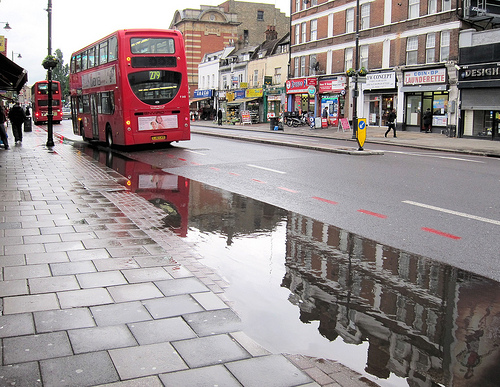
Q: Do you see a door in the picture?
A: Yes, there is a door.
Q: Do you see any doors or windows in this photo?
A: Yes, there is a door.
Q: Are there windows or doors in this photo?
A: Yes, there is a door.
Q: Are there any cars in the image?
A: No, there are no cars.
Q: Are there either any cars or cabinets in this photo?
A: No, there are no cars or cabinets.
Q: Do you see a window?
A: Yes, there is a window.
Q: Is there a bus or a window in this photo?
A: Yes, there is a window.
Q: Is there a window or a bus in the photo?
A: Yes, there is a window.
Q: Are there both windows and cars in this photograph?
A: No, there is a window but no cars.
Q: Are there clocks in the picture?
A: No, there are no clocks.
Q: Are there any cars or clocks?
A: No, there are no clocks or cars.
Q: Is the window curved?
A: Yes, the window is curved.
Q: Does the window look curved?
A: Yes, the window is curved.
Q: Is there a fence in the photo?
A: No, there are no fences.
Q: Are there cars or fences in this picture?
A: No, there are no fences or cars.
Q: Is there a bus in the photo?
A: Yes, there is a bus.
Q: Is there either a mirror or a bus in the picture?
A: Yes, there is a bus.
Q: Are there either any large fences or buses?
A: Yes, there is a large bus.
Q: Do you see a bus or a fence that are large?
A: Yes, the bus is large.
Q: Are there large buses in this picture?
A: Yes, there is a large bus.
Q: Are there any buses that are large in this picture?
A: Yes, there is a large bus.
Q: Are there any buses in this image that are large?
A: Yes, there is a bus that is large.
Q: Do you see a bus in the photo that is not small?
A: Yes, there is a large bus.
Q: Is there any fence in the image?
A: No, there are no fences.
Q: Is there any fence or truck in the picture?
A: No, there are no fences or trucks.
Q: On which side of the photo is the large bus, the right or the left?
A: The bus is on the left of the image.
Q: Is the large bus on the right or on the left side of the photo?
A: The bus is on the left of the image.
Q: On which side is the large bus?
A: The bus is on the left of the image.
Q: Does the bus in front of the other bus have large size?
A: Yes, the bus is large.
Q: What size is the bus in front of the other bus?
A: The bus is large.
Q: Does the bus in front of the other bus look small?
A: No, the bus is large.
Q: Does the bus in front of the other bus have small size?
A: No, the bus is large.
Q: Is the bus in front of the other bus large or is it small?
A: The bus is large.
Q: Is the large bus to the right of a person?
A: Yes, the bus is to the right of a person.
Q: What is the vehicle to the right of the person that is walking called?
A: The vehicle is a bus.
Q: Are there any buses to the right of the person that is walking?
A: Yes, there is a bus to the right of the person.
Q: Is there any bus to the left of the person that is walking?
A: No, the bus is to the right of the person.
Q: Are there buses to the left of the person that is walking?
A: No, the bus is to the right of the person.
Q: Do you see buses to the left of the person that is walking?
A: No, the bus is to the right of the person.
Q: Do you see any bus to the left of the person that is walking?
A: No, the bus is to the right of the person.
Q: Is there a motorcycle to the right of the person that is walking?
A: No, there is a bus to the right of the person.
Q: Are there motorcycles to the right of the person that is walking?
A: No, there is a bus to the right of the person.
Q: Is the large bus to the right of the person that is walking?
A: Yes, the bus is to the right of the person.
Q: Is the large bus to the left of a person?
A: No, the bus is to the right of a person.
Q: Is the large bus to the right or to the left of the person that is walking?
A: The bus is to the right of the person.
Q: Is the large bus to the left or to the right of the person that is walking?
A: The bus is to the right of the person.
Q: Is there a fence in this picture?
A: No, there are no fences.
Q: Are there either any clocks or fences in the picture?
A: No, there are no fences or clocks.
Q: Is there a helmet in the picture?
A: No, there are no helmets.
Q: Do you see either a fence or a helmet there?
A: No, there are no helmets or fences.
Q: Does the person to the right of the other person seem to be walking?
A: Yes, the person is walking.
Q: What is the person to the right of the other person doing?
A: The person is walking.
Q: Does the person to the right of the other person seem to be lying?
A: No, the person is walking.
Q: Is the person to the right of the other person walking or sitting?
A: The person is walking.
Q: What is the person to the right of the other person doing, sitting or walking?
A: The person is walking.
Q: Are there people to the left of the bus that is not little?
A: Yes, there is a person to the left of the bus.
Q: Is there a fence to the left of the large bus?
A: No, there is a person to the left of the bus.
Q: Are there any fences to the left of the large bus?
A: No, there is a person to the left of the bus.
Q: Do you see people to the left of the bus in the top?
A: Yes, there is a person to the left of the bus.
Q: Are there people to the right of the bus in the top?
A: No, the person is to the left of the bus.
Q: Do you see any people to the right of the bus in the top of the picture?
A: No, the person is to the left of the bus.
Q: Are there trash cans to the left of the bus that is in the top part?
A: No, there is a person to the left of the bus.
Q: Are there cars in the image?
A: No, there are no cars.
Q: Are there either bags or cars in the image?
A: No, there are no cars or bags.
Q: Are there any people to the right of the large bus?
A: No, the person is to the left of the bus.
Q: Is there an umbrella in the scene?
A: No, there are no umbrellas.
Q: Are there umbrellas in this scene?
A: No, there are no umbrellas.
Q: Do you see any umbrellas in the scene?
A: No, there are no umbrellas.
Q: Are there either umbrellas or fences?
A: No, there are no umbrellas or fences.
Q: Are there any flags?
A: Yes, there is a flag.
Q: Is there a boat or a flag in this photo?
A: Yes, there is a flag.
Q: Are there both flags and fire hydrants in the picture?
A: No, there is a flag but no fire hydrants.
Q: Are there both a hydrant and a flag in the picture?
A: No, there is a flag but no fire hydrants.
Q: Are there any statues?
A: No, there are no statues.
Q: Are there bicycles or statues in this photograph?
A: No, there are no statues or bicycles.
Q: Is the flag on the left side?
A: No, the flag is on the right of the image.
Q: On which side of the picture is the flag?
A: The flag is on the right of the image.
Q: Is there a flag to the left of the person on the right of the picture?
A: Yes, there is a flag to the left of the person.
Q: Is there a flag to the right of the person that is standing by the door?
A: No, the flag is to the left of the person.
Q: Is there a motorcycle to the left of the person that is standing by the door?
A: No, there is a flag to the left of the person.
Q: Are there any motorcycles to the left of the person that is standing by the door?
A: No, there is a flag to the left of the person.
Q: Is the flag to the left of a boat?
A: No, the flag is to the left of the person.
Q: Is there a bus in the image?
A: Yes, there is a bus.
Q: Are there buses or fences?
A: Yes, there is a bus.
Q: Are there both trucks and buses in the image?
A: No, there is a bus but no trucks.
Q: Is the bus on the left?
A: Yes, the bus is on the left of the image.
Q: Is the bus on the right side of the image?
A: No, the bus is on the left of the image.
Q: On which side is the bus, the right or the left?
A: The bus is on the left of the image.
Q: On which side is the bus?
A: The bus is on the left of the image.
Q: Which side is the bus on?
A: The bus is on the left of the image.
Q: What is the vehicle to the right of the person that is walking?
A: The vehicle is a bus.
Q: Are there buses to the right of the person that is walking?
A: Yes, there is a bus to the right of the person.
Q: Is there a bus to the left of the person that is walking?
A: No, the bus is to the right of the person.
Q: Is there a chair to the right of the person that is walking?
A: No, there is a bus to the right of the person.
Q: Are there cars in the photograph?
A: No, there are no cars.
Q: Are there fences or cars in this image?
A: No, there are no cars or fences.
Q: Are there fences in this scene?
A: No, there are no fences.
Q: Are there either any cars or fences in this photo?
A: No, there are no fences or cars.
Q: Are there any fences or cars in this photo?
A: No, there are no fences or cars.